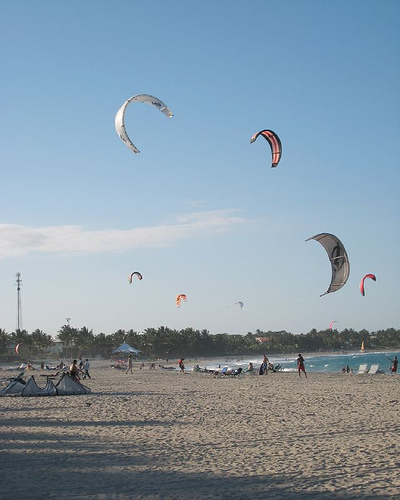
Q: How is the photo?
A: Clear.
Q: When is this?
A: Daytime.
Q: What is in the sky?
A: Parachutes.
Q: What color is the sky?
A: Blue.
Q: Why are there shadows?
A: Light.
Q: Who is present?
A: People.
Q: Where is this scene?
A: On the coast.